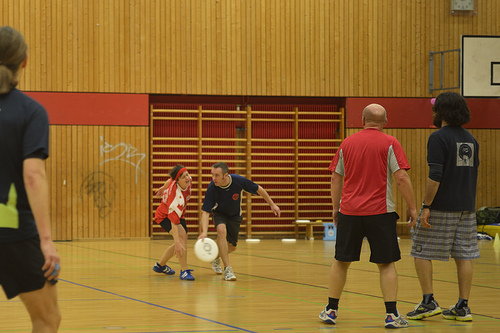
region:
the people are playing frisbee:
[132, 142, 255, 282]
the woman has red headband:
[151, 159, 208, 202]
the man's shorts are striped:
[411, 202, 489, 271]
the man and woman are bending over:
[143, 151, 280, 246]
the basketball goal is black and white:
[455, 22, 497, 117]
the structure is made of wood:
[148, 100, 340, 237]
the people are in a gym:
[1, 2, 496, 321]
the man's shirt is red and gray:
[325, 123, 417, 215]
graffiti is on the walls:
[59, 126, 156, 236]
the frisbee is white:
[184, 234, 263, 281]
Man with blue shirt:
[194, 162, 280, 279]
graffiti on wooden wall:
[80, 136, 147, 220]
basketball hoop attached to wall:
[423, 31, 498, 101]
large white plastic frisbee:
[194, 236, 217, 263]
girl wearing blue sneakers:
[151, 163, 197, 287]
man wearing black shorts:
[318, 102, 415, 329]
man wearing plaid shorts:
[401, 92, 483, 322]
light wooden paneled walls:
[1, 1, 498, 238]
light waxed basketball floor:
[1, 236, 498, 332]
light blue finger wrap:
[50, 259, 60, 281]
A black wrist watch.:
[421, 203, 431, 212]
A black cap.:
[437, 92, 470, 124]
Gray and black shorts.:
[415, 210, 477, 265]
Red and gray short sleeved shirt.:
[335, 128, 413, 221]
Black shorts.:
[336, 208, 407, 263]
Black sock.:
[326, 298, 342, 311]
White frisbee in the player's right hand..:
[195, 237, 216, 257]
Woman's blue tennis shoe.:
[178, 270, 193, 281]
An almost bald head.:
[362, 103, 388, 124]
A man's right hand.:
[407, 205, 419, 222]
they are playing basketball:
[150, 159, 268, 290]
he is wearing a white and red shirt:
[149, 159, 203, 276]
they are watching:
[323, 88, 481, 312]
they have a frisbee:
[150, 159, 277, 309]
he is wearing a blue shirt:
[199, 158, 271, 280]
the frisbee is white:
[185, 227, 225, 274]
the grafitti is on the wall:
[66, 127, 157, 223]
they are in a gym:
[25, 45, 465, 331]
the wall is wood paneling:
[65, 21, 422, 71]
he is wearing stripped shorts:
[407, 95, 498, 275]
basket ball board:
[478, 47, 486, 57]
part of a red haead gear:
[170, 169, 182, 189]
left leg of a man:
[336, 263, 340, 270]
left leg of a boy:
[423, 255, 428, 279]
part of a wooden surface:
[288, 250, 292, 275]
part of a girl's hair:
[11, 42, 19, 52]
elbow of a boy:
[433, 167, 438, 178]